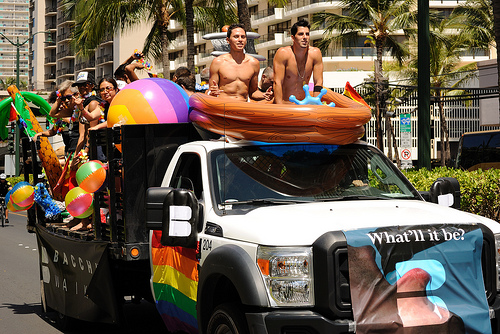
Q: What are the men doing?
A: Standing.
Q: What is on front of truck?
A: Banner.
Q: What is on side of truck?
A: Rainbow.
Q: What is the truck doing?
A: Riding in parade.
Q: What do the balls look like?
A: Beach balls.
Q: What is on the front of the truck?
A: Banner.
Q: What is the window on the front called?
A: Windshield.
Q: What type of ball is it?
A: Beach.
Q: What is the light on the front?
A: Headlight.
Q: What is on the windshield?
A: Windshield wipers.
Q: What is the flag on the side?
A: Rainbow.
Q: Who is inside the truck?
A: Driver.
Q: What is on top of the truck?
A: Two men.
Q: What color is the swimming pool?
A: Orange.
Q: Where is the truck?
A: On the road.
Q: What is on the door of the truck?
A: Gay Pride flag.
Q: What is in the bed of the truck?
A: People, beach balls.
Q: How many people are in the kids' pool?
A: Two.